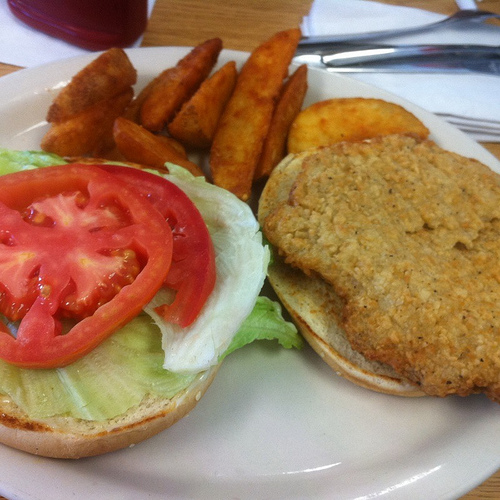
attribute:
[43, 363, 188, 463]
bun — toasted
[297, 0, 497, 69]
napkin — paper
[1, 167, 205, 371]
tomato — sliced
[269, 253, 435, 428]
bun — toasted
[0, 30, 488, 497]
plate — white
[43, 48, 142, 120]
potato wedges — brown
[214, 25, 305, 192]
potato wedges — brown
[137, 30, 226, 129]
potato wedges — brown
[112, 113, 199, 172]
potato wedges — brown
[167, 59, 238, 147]
potato wedges — brown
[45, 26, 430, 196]
potato wedges — fried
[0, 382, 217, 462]
bun — toasted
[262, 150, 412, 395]
bun — toasted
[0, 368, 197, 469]
bun — browned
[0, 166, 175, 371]
tomato — sliced, red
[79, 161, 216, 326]
tomato — red, sliced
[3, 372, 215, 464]
bun — grilled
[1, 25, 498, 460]
lunch — nice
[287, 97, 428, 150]
potato wedge — lighter colored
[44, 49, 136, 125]
french fry — batter dipped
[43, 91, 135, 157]
french fry — batter dipped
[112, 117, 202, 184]
french fry — batter dipped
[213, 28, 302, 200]
french fry — batter dipped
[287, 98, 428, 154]
french fry — batter dipped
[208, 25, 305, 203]
potato wedge — long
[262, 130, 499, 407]
pork patty — battered, seasoned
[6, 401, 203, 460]
bun — grilled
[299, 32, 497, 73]
utensils — silver